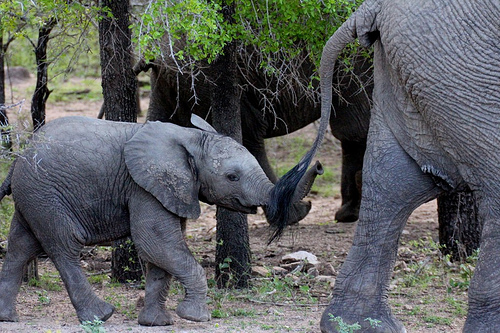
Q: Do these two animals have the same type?
A: Yes, all the animals are elephants.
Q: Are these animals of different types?
A: No, all the animals are elephants.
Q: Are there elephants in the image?
A: Yes, there is an elephant.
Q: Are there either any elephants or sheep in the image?
A: Yes, there is an elephant.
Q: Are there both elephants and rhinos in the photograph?
A: No, there is an elephant but no rhinos.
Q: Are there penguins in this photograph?
A: No, there are no penguins.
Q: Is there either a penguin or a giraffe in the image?
A: No, there are no penguins or giraffes.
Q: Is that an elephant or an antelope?
A: That is an elephant.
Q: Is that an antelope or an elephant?
A: That is an elephant.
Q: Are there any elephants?
A: Yes, there is an elephant.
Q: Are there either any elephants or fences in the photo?
A: Yes, there is an elephant.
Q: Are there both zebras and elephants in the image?
A: No, there is an elephant but no zebras.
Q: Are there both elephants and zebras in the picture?
A: No, there is an elephant but no zebras.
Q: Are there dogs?
A: No, there are no dogs.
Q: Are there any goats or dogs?
A: No, there are no dogs or goats.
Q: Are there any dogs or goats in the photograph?
A: No, there are no dogs or goats.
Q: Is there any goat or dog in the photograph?
A: No, there are no dogs or goats.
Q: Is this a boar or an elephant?
A: This is an elephant.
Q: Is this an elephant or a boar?
A: This is an elephant.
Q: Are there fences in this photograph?
A: No, there are no fences.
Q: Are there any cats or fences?
A: No, there are no fences or cats.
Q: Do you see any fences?
A: No, there are no fences.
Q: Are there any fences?
A: No, there are no fences.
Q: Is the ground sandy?
A: Yes, the ground is sandy.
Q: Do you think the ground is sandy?
A: Yes, the ground is sandy.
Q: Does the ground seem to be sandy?
A: Yes, the ground is sandy.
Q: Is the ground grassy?
A: No, the ground is sandy.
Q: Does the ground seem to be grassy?
A: No, the ground is sandy.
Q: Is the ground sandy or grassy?
A: The ground is sandy.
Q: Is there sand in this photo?
A: Yes, there is sand.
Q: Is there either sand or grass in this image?
A: Yes, there is sand.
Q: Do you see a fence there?
A: No, there are no fences.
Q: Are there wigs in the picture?
A: No, there are no wigs.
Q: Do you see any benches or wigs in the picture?
A: No, there are no wigs or benches.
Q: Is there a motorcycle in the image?
A: No, there are no motorcycles.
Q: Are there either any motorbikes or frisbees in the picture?
A: No, there are no motorbikes or frisbees.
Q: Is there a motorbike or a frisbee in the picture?
A: No, there are no motorcycles or frisbees.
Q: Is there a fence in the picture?
A: No, there are no fences.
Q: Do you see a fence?
A: No, there are no fences.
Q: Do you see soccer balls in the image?
A: No, there are no soccer balls.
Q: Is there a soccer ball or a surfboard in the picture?
A: No, there are no soccer balls or surfboards.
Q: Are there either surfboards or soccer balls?
A: No, there are no soccer balls or surfboards.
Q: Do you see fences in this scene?
A: No, there are no fences.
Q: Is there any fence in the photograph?
A: No, there are no fences.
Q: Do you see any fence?
A: No, there are no fences.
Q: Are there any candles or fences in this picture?
A: No, there are no fences or candles.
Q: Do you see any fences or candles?
A: No, there are no fences or candles.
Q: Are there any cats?
A: No, there are no cats.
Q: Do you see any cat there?
A: No, there are no cats.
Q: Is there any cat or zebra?
A: No, there are no cats or zebras.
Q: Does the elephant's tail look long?
A: Yes, the tail is long.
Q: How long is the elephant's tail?
A: The tail is long.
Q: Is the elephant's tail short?
A: No, the tail is long.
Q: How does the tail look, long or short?
A: The tail is long.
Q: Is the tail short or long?
A: The tail is long.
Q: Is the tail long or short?
A: The tail is long.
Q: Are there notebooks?
A: No, there are no notebooks.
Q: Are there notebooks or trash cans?
A: No, there are no notebooks or trash cans.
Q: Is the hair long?
A: Yes, the hair is long.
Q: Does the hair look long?
A: Yes, the hair is long.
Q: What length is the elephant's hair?
A: The hair is long.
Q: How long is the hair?
A: The hair is long.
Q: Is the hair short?
A: No, the hair is long.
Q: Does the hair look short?
A: No, the hair is long.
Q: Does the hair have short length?
A: No, the hair is long.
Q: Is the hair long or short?
A: The hair is long.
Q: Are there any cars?
A: No, there are no cars.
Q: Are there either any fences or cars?
A: No, there are no cars or fences.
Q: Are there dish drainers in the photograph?
A: No, there are no dish drainers.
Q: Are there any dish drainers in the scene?
A: No, there are no dish drainers.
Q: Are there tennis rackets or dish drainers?
A: No, there are no dish drainers or tennis rackets.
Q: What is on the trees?
A: The leaves are on the trees.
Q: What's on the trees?
A: The leaves are on the trees.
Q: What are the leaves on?
A: The leaves are on the trees.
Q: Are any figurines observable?
A: No, there are no figurines.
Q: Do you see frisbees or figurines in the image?
A: No, there are no figurines or frisbees.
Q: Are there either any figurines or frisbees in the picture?
A: No, there are no figurines or frisbees.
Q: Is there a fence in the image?
A: No, there are no fences.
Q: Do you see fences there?
A: No, there are no fences.